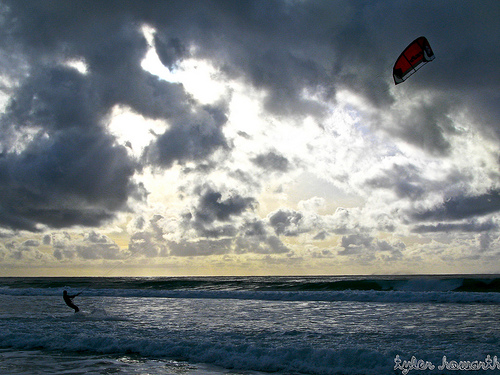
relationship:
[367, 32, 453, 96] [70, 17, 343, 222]
kite in sky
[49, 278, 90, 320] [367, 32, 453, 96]
man flying kite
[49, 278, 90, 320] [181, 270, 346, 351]
man in water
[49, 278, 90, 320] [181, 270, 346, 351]
man on water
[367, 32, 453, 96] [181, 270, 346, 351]
kite above water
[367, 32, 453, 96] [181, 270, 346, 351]
kite near water